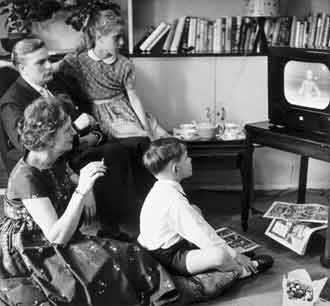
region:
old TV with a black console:
[267, 46, 329, 136]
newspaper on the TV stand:
[263, 198, 329, 224]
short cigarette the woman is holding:
[99, 156, 103, 164]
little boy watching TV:
[136, 138, 268, 275]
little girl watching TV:
[0, 14, 174, 146]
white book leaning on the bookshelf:
[141, 22, 164, 50]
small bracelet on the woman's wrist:
[74, 187, 87, 197]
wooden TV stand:
[239, 121, 327, 262]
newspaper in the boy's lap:
[212, 225, 261, 254]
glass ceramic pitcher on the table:
[193, 118, 225, 138]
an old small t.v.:
[267, 46, 329, 128]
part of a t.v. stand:
[239, 121, 328, 223]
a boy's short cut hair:
[144, 135, 184, 175]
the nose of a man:
[43, 59, 53, 69]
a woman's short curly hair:
[14, 92, 73, 155]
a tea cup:
[180, 129, 196, 139]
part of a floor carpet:
[198, 181, 240, 228]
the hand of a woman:
[74, 162, 108, 191]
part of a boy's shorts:
[141, 247, 191, 272]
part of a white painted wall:
[136, 60, 210, 108]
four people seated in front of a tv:
[2, 12, 269, 305]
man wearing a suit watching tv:
[2, 38, 105, 148]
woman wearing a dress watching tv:
[3, 95, 176, 301]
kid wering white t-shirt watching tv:
[132, 136, 271, 275]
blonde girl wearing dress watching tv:
[54, 8, 170, 140]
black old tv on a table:
[266, 46, 329, 125]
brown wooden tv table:
[241, 118, 328, 260]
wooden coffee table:
[142, 116, 252, 230]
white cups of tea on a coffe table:
[173, 119, 236, 139]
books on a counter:
[138, 14, 329, 54]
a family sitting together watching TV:
[3, 10, 325, 299]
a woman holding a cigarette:
[4, 93, 110, 257]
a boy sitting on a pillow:
[130, 139, 275, 301]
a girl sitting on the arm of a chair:
[60, 8, 174, 150]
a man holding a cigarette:
[1, 36, 103, 149]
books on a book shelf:
[137, 4, 327, 54]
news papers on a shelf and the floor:
[208, 186, 325, 257]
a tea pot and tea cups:
[171, 106, 252, 147]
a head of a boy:
[138, 132, 203, 188]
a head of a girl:
[72, 6, 132, 65]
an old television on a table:
[266, 45, 326, 135]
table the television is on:
[239, 117, 324, 262]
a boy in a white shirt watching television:
[134, 134, 269, 272]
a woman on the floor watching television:
[0, 94, 173, 301]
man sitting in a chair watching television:
[0, 35, 148, 235]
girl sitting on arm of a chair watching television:
[0, 4, 172, 136]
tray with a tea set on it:
[165, 103, 244, 147]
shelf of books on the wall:
[124, 0, 324, 55]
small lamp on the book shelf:
[238, 0, 283, 50]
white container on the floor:
[280, 267, 325, 303]